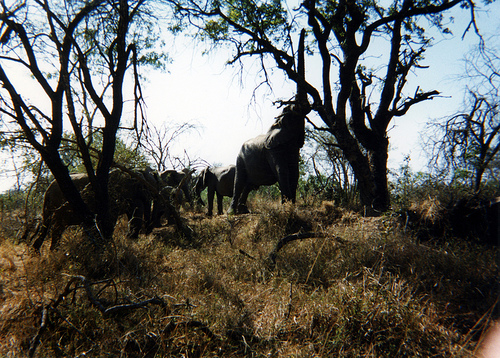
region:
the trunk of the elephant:
[288, 22, 314, 106]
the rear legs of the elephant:
[224, 177, 253, 217]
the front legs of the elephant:
[273, 161, 305, 208]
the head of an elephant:
[265, 97, 315, 147]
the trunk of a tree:
[351, 145, 406, 217]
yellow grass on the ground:
[1, 197, 497, 354]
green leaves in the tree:
[194, 0, 296, 44]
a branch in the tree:
[236, 51, 276, 121]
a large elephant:
[218, 24, 310, 216]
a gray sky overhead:
[1, 0, 498, 190]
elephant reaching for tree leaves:
[227, 25, 327, 234]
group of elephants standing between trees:
[15, 24, 345, 257]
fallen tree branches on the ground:
[12, 221, 262, 354]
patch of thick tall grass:
[2, 217, 497, 357]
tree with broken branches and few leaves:
[1, 0, 149, 285]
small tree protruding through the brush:
[428, 31, 498, 216]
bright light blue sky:
[1, 1, 496, 200]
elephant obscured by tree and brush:
[15, 161, 163, 256]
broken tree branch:
[254, 216, 364, 291]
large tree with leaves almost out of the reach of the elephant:
[161, 0, 487, 227]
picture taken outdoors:
[41, 29, 436, 356]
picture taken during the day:
[36, 10, 437, 353]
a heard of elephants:
[27, 82, 417, 313]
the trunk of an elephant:
[273, 18, 349, 170]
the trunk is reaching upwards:
[282, 25, 348, 191]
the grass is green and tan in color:
[87, 227, 492, 338]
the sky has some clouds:
[432, 53, 448, 86]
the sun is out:
[167, 80, 261, 157]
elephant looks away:
[183, 156, 213, 217]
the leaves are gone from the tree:
[435, 70, 495, 195]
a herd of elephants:
[16, 33, 363, 265]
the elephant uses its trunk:
[205, 12, 409, 255]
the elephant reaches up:
[238, 67, 355, 241]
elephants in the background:
[150, 134, 285, 237]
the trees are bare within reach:
[215, 3, 465, 222]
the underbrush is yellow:
[244, 230, 356, 282]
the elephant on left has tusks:
[2, 142, 352, 265]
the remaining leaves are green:
[183, 15, 296, 90]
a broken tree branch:
[99, 29, 179, 169]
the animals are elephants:
[29, 95, 382, 250]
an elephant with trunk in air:
[183, 6, 420, 242]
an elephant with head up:
[165, 25, 354, 248]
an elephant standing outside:
[179, 27, 368, 256]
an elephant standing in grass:
[205, 32, 392, 241]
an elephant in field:
[162, 28, 412, 300]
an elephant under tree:
[207, 11, 439, 323]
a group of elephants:
[23, 21, 412, 293]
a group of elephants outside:
[41, 54, 351, 266]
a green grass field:
[160, 228, 465, 345]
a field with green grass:
[98, 220, 425, 356]